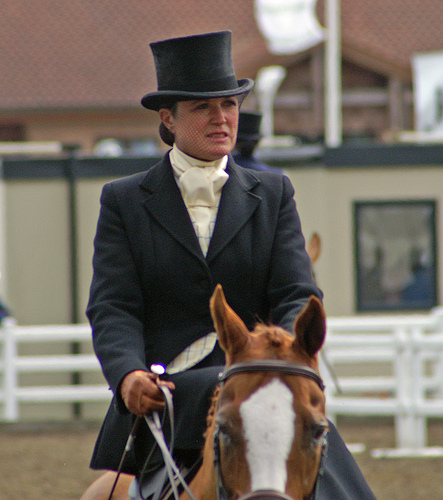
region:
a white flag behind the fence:
[264, 2, 323, 56]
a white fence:
[17, 323, 436, 413]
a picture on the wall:
[360, 195, 434, 303]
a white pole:
[320, 18, 339, 135]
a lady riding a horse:
[87, 27, 337, 471]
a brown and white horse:
[211, 325, 338, 487]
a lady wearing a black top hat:
[69, 25, 378, 431]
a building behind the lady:
[14, 134, 438, 350]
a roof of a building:
[3, 1, 440, 130]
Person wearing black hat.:
[147, 23, 233, 93]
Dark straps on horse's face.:
[203, 357, 316, 482]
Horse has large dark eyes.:
[207, 408, 332, 445]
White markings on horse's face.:
[238, 385, 289, 498]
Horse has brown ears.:
[201, 320, 359, 347]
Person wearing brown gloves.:
[116, 359, 165, 408]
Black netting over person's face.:
[163, 95, 260, 160]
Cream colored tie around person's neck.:
[181, 162, 222, 217]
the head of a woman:
[135, 4, 278, 180]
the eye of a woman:
[190, 88, 254, 129]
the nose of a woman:
[200, 110, 234, 134]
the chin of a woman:
[202, 129, 252, 165]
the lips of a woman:
[202, 126, 237, 148]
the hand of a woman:
[111, 330, 215, 437]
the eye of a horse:
[206, 400, 258, 452]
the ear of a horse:
[187, 256, 366, 374]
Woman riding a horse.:
[77, 25, 383, 497]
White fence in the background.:
[3, 305, 442, 460]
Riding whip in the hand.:
[103, 357, 168, 499]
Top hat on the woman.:
[136, 26, 260, 172]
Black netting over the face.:
[143, 81, 256, 162]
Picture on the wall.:
[347, 193, 441, 314]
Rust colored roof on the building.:
[0, 0, 441, 108]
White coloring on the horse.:
[206, 286, 326, 498]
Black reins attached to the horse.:
[139, 379, 210, 497]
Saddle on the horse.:
[123, 462, 200, 498]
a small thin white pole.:
[314, 0, 352, 146]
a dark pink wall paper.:
[12, 2, 126, 87]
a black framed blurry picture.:
[349, 195, 442, 318]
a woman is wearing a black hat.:
[139, 31, 256, 113]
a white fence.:
[0, 313, 86, 427]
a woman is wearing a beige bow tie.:
[166, 149, 233, 223]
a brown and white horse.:
[188, 282, 339, 497]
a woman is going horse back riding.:
[74, 26, 375, 498]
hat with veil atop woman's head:
[139, 29, 254, 158]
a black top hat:
[132, 29, 254, 108]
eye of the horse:
[218, 418, 234, 438]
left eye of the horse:
[305, 420, 331, 437]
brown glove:
[115, 372, 178, 407]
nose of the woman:
[206, 112, 229, 127]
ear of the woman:
[154, 106, 178, 135]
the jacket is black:
[64, 160, 338, 406]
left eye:
[221, 97, 236, 112]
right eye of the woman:
[190, 102, 214, 115]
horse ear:
[207, 281, 246, 343]